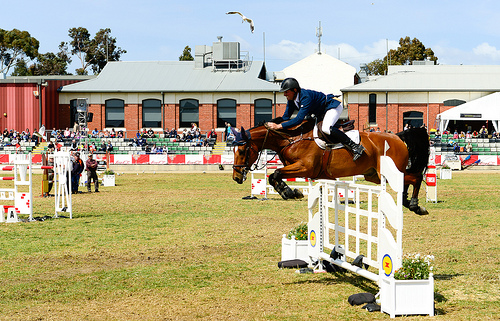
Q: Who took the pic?
A: Photographer.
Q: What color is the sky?
A: Blue.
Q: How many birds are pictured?
A: One.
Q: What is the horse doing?
A: Jumping.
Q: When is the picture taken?
A: Daytime.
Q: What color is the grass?
A: Green.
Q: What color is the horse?
A: Brown.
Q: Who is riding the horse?
A: A jockey.